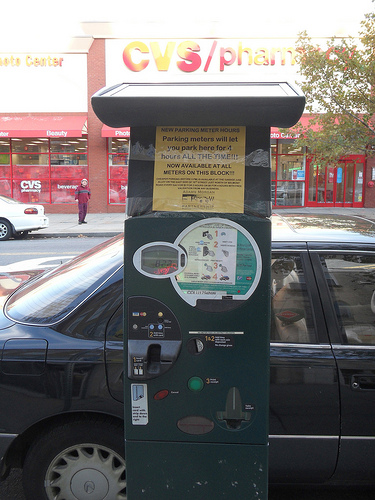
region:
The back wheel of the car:
[14, 414, 137, 498]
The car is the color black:
[293, 372, 360, 461]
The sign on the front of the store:
[117, 35, 363, 78]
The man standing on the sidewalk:
[68, 170, 99, 228]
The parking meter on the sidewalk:
[85, 65, 315, 498]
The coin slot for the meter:
[184, 331, 211, 362]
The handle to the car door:
[341, 365, 373, 395]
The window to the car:
[319, 245, 373, 346]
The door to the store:
[304, 155, 373, 211]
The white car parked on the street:
[0, 193, 51, 240]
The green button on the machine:
[183, 377, 204, 395]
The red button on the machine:
[152, 389, 164, 404]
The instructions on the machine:
[168, 228, 260, 313]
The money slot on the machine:
[131, 329, 177, 384]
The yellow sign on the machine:
[159, 128, 234, 215]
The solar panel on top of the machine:
[109, 75, 312, 132]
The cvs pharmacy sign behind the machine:
[118, 46, 328, 98]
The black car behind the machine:
[4, 220, 371, 498]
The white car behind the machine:
[2, 191, 42, 238]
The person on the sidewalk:
[72, 180, 96, 225]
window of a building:
[9, 141, 44, 149]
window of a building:
[57, 138, 92, 150]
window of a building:
[0, 134, 12, 148]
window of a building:
[97, 146, 120, 167]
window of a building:
[107, 138, 130, 147]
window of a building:
[274, 133, 301, 155]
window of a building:
[272, 154, 302, 179]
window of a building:
[271, 182, 302, 206]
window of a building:
[313, 170, 326, 201]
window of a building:
[337, 156, 371, 208]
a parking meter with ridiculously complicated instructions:
[85, 72, 306, 447]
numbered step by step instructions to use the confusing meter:
[165, 210, 263, 315]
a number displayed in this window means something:
[127, 236, 187, 277]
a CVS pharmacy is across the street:
[110, 27, 365, 73]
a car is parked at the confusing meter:
[0, 203, 371, 497]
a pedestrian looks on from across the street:
[70, 173, 93, 228]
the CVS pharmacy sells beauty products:
[39, 125, 74, 141]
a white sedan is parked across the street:
[0, 186, 50, 243]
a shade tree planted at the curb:
[290, 2, 374, 237]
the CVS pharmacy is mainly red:
[1, 107, 371, 212]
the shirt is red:
[80, 194, 86, 200]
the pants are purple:
[77, 206, 87, 215]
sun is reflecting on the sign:
[148, 41, 174, 61]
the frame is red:
[303, 158, 312, 186]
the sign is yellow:
[188, 149, 216, 170]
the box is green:
[239, 354, 256, 371]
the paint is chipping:
[223, 465, 256, 494]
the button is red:
[155, 390, 165, 400]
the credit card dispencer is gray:
[132, 342, 146, 355]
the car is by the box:
[104, 369, 142, 412]